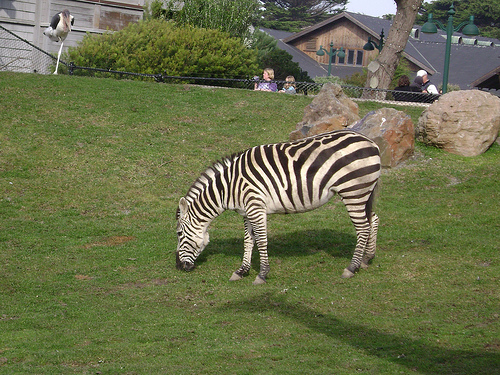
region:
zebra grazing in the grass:
[157, 124, 393, 295]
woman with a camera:
[251, 62, 278, 95]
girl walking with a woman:
[278, 71, 298, 96]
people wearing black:
[393, 72, 430, 107]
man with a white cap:
[415, 67, 440, 99]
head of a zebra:
[167, 191, 213, 276]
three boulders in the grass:
[283, 77, 499, 174]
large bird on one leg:
[38, 7, 83, 79]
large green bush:
[62, 15, 262, 94]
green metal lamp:
[312, 39, 348, 100]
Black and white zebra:
[136, 115, 408, 290]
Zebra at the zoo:
[92, 3, 464, 311]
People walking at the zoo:
[172, 32, 459, 292]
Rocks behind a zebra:
[195, 86, 499, 286]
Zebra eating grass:
[111, 187, 283, 336]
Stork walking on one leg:
[13, 3, 121, 113]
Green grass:
[18, 97, 152, 213]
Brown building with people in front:
[225, 13, 499, 133]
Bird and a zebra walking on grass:
[1, 10, 408, 282]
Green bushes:
[67, 2, 261, 122]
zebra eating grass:
[171, 131, 384, 282]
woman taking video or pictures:
[249, 63, 280, 92]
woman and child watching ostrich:
[250, 66, 300, 91]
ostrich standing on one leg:
[38, 8, 76, 75]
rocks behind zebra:
[291, 80, 496, 153]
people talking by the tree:
[392, 68, 439, 99]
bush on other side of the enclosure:
[81, 20, 253, 83]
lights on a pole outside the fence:
[420, 1, 481, 86]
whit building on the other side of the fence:
[1, 1, 125, 73]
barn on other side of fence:
[248, 12, 498, 88]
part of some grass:
[306, 320, 367, 360]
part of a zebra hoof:
[248, 275, 269, 289]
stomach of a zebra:
[291, 197, 316, 217]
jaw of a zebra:
[197, 235, 209, 252]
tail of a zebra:
[363, 187, 381, 227]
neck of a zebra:
[176, 175, 227, 227]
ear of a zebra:
[169, 195, 194, 220]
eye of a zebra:
[165, 220, 189, 238]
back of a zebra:
[258, 133, 325, 164]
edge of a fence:
[275, 72, 308, 94]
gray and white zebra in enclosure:
[153, 101, 388, 293]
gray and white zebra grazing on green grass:
[163, 109, 390, 313]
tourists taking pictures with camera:
[238, 54, 302, 100]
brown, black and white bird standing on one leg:
[31, 11, 86, 74]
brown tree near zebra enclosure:
[380, 6, 418, 97]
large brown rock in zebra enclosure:
[420, 70, 496, 156]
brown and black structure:
[279, 7, 377, 67]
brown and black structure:
[424, 17, 491, 79]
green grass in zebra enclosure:
[8, 94, 169, 355]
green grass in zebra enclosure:
[390, 175, 485, 360]